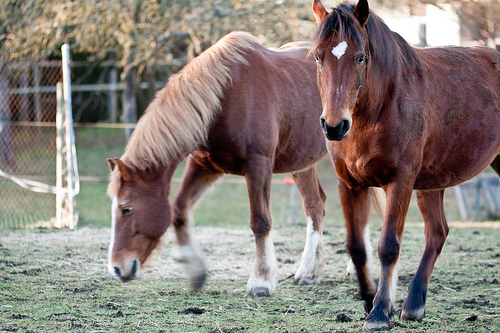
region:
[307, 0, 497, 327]
A brown horse walking.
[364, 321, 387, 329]
The hoof on the horse.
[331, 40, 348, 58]
A white spot on the horse's face.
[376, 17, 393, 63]
part of the brown mane.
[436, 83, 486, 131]
The horse's brown fur.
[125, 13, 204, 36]
Part of a tree.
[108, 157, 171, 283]
The head of the horse.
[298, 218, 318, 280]
A white part on the leg.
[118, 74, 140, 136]
Part of a tree trunk.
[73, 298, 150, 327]
Part of the grass.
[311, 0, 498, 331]
A large brown horse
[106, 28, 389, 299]
A large brown horse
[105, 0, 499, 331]
A pair of horses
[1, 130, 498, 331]
A grassy landscape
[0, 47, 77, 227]
a chain link fence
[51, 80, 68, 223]
a short metal pole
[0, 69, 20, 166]
a large tree trunk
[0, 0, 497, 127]
some overhanging tree branches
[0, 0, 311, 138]
A large tree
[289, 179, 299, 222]
a metal pole in the ground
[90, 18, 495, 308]
two horses standing next to each other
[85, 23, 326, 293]
a brown and white horse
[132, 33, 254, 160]
a horse with a blonde mane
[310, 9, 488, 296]
a brown and black horse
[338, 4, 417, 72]
a horse with a brown and black mane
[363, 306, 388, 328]
the hoof of a horse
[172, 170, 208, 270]
the right front leg of a horse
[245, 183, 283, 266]
the left front leg of a horse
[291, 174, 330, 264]
the right rear leg of a horse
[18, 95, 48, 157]
a chain link fence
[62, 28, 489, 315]
Two horses standing together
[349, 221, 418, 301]
Horse has black patches on its leg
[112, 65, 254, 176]
Horse has a long mane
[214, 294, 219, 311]
The grass is very short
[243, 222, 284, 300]
Horse has furry feet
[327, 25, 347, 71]
White patch on horses head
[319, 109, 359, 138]
Black area on horses nose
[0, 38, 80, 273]
Fence surrounding the horses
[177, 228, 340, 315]
Horse has four hooves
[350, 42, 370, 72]
Horse has dark eyes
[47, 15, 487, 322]
horses on the grass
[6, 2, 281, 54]
trees behind the horses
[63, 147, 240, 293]
the horse eating hay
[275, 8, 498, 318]
the horse is looking at camera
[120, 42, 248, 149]
the horse has blonde mane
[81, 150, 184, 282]
head of the horse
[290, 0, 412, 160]
head of the horse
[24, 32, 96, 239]
the metal fence post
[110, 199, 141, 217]
eye of the horse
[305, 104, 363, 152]
nostrils of the horse